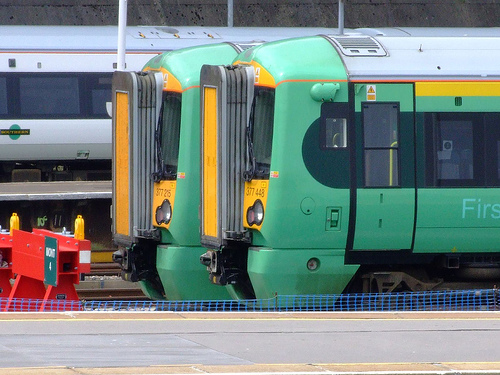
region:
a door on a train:
[343, 76, 423, 263]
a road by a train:
[0, 302, 495, 367]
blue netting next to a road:
[0, 277, 495, 307]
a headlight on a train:
[240, 195, 262, 225]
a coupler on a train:
[200, 245, 226, 275]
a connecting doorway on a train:
[197, 57, 249, 258]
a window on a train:
[422, 106, 487, 187]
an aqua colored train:
[194, 24, 495, 303]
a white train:
[3, 16, 498, 195]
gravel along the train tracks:
[82, 263, 122, 287]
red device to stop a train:
[3, 207, 114, 316]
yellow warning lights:
[62, 210, 89, 255]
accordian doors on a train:
[104, 57, 251, 266]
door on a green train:
[342, 75, 425, 260]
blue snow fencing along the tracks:
[69, 287, 461, 306]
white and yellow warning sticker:
[363, 78, 382, 107]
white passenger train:
[5, 19, 115, 210]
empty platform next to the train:
[61, 317, 482, 361]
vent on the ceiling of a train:
[325, 30, 392, 77]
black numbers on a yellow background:
[243, 182, 273, 200]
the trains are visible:
[112, 28, 488, 312]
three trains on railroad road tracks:
[0, 23, 497, 310]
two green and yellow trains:
[110, 35, 498, 307]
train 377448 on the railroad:
[199, 35, 499, 308]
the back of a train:
[109, 40, 198, 305]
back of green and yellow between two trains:
[110, 40, 201, 298]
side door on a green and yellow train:
[345, 81, 416, 263]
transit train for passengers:
[0, 49, 110, 180]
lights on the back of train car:
[245, 198, 264, 228]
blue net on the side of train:
[0, 290, 497, 310]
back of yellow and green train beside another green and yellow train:
[110, 40, 197, 300]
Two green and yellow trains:
[101, 39, 476, 302]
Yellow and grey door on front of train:
[181, 50, 258, 252]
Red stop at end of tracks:
[8, 212, 105, 311]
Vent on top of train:
[322, 15, 399, 73]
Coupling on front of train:
[196, 238, 256, 295]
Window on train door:
[356, 90, 408, 202]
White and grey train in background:
[1, 15, 110, 237]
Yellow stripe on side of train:
[410, 73, 499, 111]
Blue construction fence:
[2, 287, 494, 323]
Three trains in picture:
[3, 5, 497, 312]